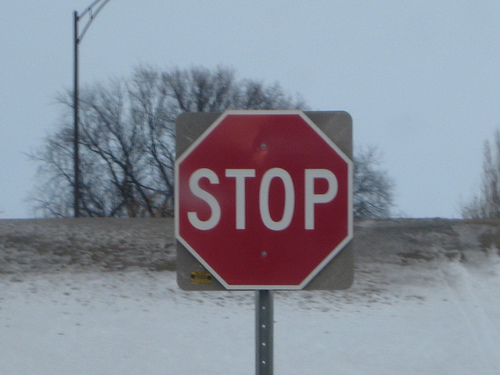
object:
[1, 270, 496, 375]
snow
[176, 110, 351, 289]
stop sign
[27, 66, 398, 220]
trees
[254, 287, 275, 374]
pole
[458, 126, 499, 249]
shrubbery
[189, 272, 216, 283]
sticker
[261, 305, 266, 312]
hole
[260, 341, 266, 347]
hole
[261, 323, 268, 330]
hole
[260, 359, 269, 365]
hole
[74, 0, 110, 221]
light pole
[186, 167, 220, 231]
letter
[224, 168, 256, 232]
letter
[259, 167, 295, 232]
letter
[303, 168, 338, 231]
letter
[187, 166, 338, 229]
word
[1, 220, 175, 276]
grass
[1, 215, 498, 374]
ground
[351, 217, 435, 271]
sandy area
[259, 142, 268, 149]
screw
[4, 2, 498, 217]
sky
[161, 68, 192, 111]
branches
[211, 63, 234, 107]
branches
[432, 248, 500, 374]
car tracks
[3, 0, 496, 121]
clouds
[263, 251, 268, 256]
bottom screw